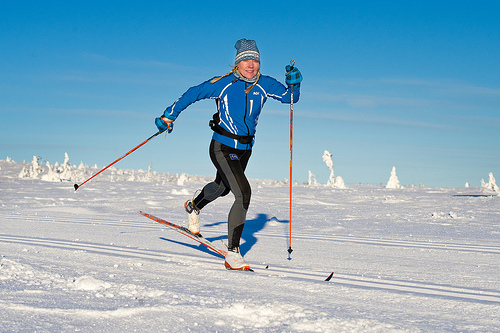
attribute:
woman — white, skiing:
[150, 35, 314, 280]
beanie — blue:
[226, 37, 269, 66]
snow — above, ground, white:
[4, 159, 496, 332]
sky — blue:
[2, 2, 496, 188]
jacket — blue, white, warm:
[154, 68, 311, 155]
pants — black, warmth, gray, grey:
[179, 136, 269, 256]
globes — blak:
[274, 245, 296, 259]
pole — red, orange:
[284, 86, 306, 261]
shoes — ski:
[174, 197, 246, 276]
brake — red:
[134, 206, 195, 237]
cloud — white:
[50, 45, 477, 158]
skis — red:
[130, 208, 344, 304]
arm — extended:
[149, 71, 242, 143]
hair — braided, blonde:
[212, 63, 267, 96]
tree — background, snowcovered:
[380, 164, 410, 193]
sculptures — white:
[21, 152, 201, 202]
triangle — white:
[377, 162, 407, 190]